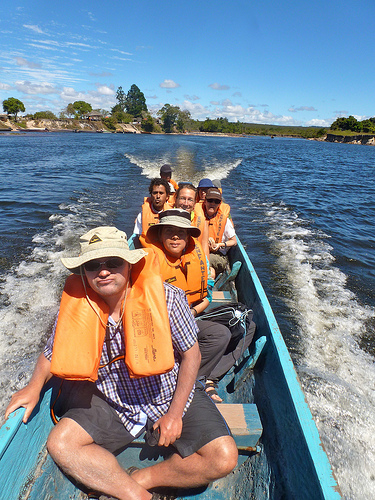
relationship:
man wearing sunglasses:
[5, 224, 237, 496] [86, 260, 124, 273]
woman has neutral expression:
[145, 205, 255, 383] [164, 230, 190, 253]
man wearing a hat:
[5, 224, 237, 496] [59, 225, 150, 272]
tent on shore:
[84, 108, 105, 120] [2, 118, 148, 132]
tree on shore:
[1, 94, 28, 125] [2, 118, 148, 132]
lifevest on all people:
[48, 270, 177, 379] [27, 166, 237, 372]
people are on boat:
[27, 166, 237, 372] [1, 168, 343, 499]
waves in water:
[118, 140, 246, 178] [1, 134, 374, 450]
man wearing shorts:
[5, 224, 237, 496] [61, 386, 233, 457]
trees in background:
[3, 90, 373, 131] [1, 0, 371, 184]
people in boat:
[27, 166, 237, 372] [1, 168, 343, 499]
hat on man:
[59, 225, 150, 272] [5, 224, 237, 496]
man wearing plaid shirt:
[5, 224, 237, 496] [44, 287, 195, 432]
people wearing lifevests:
[27, 166, 237, 372] [48, 270, 177, 379]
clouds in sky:
[5, 15, 324, 125] [1, 0, 371, 184]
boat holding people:
[1, 168, 343, 499] [27, 166, 237, 372]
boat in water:
[1, 168, 343, 499] [1, 134, 374, 450]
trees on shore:
[3, 90, 373, 131] [2, 118, 148, 132]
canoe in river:
[1, 134, 374, 450] [3, 129, 374, 294]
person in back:
[159, 163, 180, 190] [145, 157, 241, 230]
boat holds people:
[1, 168, 343, 499] [27, 166, 237, 372]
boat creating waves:
[1, 168, 343, 499] [118, 140, 246, 178]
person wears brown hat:
[193, 185, 235, 255] [204, 187, 222, 206]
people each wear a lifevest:
[27, 166, 237, 372] [48, 270, 177, 379]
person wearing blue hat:
[197, 175, 220, 196] [200, 179, 212, 189]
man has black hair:
[131, 177, 171, 241] [150, 179, 169, 194]